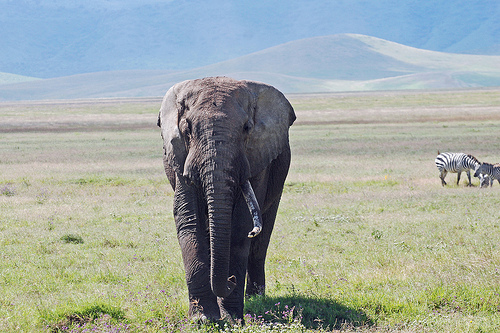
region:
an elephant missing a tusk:
[131, 66, 345, 321]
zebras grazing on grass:
[427, 141, 498, 190]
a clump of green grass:
[61, 294, 121, 329]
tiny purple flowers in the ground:
[264, 300, 303, 327]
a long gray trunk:
[201, 184, 245, 299]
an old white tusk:
[246, 186, 271, 243]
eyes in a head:
[165, 111, 251, 144]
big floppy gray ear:
[258, 86, 294, 180]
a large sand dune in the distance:
[293, 31, 423, 78]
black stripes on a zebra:
[440, 155, 462, 167]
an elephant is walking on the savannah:
[153, 71, 295, 327]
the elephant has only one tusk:
[153, 75, 293, 318]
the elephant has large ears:
[152, 75, 297, 205]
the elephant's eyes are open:
[180, 105, 256, 148]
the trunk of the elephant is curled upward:
[192, 147, 243, 298]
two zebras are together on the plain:
[426, 146, 497, 187]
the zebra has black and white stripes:
[431, 145, 484, 190]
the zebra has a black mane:
[457, 148, 482, 178]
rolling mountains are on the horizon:
[1, 5, 497, 110]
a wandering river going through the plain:
[1, 101, 498, 142]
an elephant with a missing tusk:
[150, 74, 296, 331]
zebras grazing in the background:
[434, 145, 499, 193]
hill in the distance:
[0, 18, 498, 77]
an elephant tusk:
[237, 176, 264, 246]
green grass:
[83, 300, 125, 314]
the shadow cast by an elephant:
[260, 293, 375, 326]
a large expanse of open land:
[301, 93, 498, 148]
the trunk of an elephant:
[198, 138, 242, 303]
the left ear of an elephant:
[251, 75, 297, 181]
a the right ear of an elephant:
[153, 85, 183, 176]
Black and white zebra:
[424, 143, 481, 189]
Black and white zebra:
[471, 161, 498, 186]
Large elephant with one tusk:
[124, 61, 331, 332]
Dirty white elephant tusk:
[230, 170, 269, 252]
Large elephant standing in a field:
[129, 53, 324, 331]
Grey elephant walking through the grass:
[137, 62, 324, 332]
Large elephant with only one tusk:
[122, 54, 344, 331]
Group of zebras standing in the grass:
[419, 138, 499, 198]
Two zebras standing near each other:
[408, 130, 498, 199]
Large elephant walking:
[131, 53, 332, 331]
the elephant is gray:
[122, 37, 327, 314]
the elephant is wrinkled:
[120, 73, 299, 330]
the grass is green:
[9, 191, 92, 301]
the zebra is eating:
[426, 144, 498, 211]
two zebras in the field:
[396, 100, 496, 210]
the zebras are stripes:
[433, 135, 492, 194]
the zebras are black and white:
[422, 142, 496, 202]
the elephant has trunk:
[145, 79, 272, 331]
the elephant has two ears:
[137, 70, 313, 183]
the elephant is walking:
[139, 156, 351, 331]